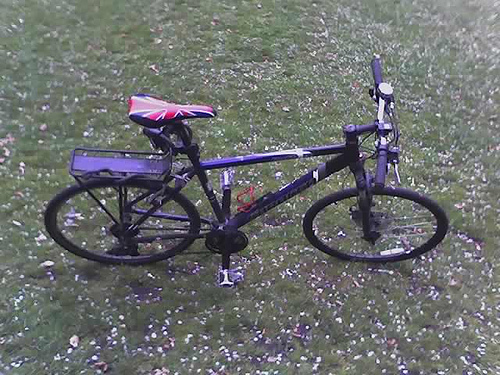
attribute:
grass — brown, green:
[118, 35, 411, 135]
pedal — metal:
[212, 260, 245, 300]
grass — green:
[209, 15, 306, 73]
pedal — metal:
[219, 167, 234, 187]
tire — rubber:
[303, 184, 450, 264]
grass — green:
[25, 295, 100, 346]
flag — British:
[127, 93, 217, 123]